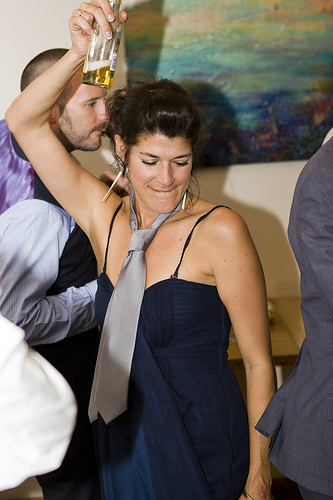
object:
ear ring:
[181, 192, 187, 211]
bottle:
[80, 1, 123, 90]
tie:
[88, 186, 188, 426]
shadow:
[121, 0, 177, 90]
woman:
[2, 0, 280, 500]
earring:
[181, 193, 187, 210]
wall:
[0, 3, 32, 53]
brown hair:
[100, 75, 206, 217]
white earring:
[101, 153, 129, 203]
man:
[0, 46, 110, 500]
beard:
[59, 113, 107, 152]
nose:
[155, 163, 175, 187]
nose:
[97, 98, 110, 122]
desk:
[223, 296, 303, 370]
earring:
[100, 153, 129, 204]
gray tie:
[88, 185, 190, 426]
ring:
[78, 10, 83, 15]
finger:
[68, 1, 129, 41]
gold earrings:
[100, 170, 187, 210]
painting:
[122, 1, 333, 168]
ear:
[114, 133, 127, 164]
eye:
[88, 102, 96, 106]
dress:
[86, 197, 252, 500]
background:
[225, 166, 287, 206]